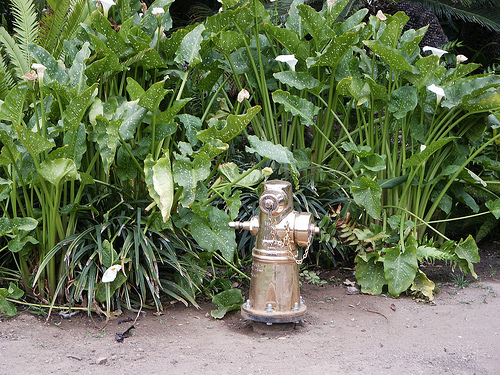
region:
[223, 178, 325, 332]
the fire hydrant is gold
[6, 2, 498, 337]
exotic plantings are behind the hydrant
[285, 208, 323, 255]
the fire hose receptacle plug is on the hydrant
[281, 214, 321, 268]
a chain is on the cap of the plug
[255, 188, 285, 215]
the hydrant drain plug has a chain attached to it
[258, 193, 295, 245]
a chain is attached to the cap of the drain plug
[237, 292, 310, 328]
bolts attach the hydrant to the water pipe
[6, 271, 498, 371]
the hydrant is on a dirt road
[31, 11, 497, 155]
white spots are on the alocasia plants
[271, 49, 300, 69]
flower bloom in the greenery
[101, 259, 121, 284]
flower bloom in the greenery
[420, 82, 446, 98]
flower bloom in the greenery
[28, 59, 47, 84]
flower bloom in the greenery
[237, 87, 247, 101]
flower bloom in the greenery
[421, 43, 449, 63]
flower bloom in the greenery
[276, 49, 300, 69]
white flower bloom in the greenery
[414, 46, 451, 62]
white flower bloom in the greenery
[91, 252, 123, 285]
white flower bloom in the greenery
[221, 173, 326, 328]
fire hydrant in front of the greenery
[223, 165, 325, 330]
Fire hydrant on the ground.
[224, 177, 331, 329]
Gold color on the fire hydrant.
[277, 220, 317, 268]
chain on the fire hydrant.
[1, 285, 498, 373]
Dirt covering the ground.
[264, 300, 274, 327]
bolt on the fire hydrant.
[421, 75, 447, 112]
White flower in the plants.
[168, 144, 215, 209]
Green leaf on the plant.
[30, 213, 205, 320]
Long green blades on the plant.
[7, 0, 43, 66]
Fern leaf in the plants.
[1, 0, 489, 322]
Shrubbery in the background.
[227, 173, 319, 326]
a fire hydrant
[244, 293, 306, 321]
metal bolts on the hydrant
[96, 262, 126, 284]
a white flower on the bush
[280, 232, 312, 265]
gold chain on the hydrant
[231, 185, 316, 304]
the hydrant is shining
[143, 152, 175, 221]
a fern leaf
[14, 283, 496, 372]
dirt on the ground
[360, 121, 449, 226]
stems on the plant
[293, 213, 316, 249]
the hydrant cap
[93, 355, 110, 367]
small rock on the ground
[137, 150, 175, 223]
big green leaf on plant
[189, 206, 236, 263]
big green leaf on plant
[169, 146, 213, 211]
big green leaf on plant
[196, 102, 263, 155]
big green leaf on plant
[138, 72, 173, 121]
big green leaf on plant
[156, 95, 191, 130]
big green leaf on plant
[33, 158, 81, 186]
big green leaf on plant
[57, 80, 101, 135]
big green leaf on plant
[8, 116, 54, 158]
big green leaf on plant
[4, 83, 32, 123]
big green leaf on plant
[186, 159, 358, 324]
golden hydrant next to grass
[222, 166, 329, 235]
top of the hydrant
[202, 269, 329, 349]
bottom of the hydrant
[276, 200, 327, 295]
side of the hydrant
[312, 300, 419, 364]
dirt on the ground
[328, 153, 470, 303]
leaves next to hydrant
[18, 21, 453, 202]
many leaves behind hydrant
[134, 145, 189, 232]
one leaf in group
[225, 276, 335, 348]
foundation of the hydrant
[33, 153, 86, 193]
a leaf on a stem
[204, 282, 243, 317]
a leaf on a stem